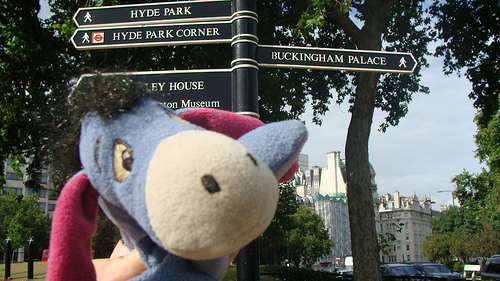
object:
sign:
[257, 41, 416, 72]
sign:
[69, 23, 235, 51]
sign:
[71, 3, 231, 21]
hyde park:
[124, 6, 191, 16]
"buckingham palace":
[265, 49, 389, 69]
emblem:
[396, 53, 412, 74]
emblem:
[262, 45, 425, 66]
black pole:
[231, 2, 258, 279]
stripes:
[228, 7, 258, 118]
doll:
[45, 84, 317, 279]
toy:
[45, 66, 312, 281]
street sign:
[66, 65, 233, 113]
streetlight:
[448, 189, 460, 209]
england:
[21, 8, 498, 268]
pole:
[232, 8, 262, 279]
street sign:
[70, 26, 247, 48]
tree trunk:
[340, 94, 382, 278]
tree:
[304, 6, 498, 279]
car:
[379, 260, 464, 280]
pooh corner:
[34, 62, 314, 279]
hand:
[107, 246, 247, 279]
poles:
[24, 218, 37, 281]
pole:
[230, 0, 259, 117]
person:
[77, 30, 90, 45]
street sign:
[258, 37, 417, 70]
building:
[368, 189, 430, 280]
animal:
[34, 99, 317, 274]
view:
[288, 150, 447, 272]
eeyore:
[37, 70, 309, 279]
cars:
[329, 262, 358, 278]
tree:
[5, 190, 49, 261]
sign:
[65, 67, 229, 114]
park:
[298, 250, 497, 277]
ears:
[232, 116, 308, 177]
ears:
[43, 169, 99, 277]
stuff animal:
[42, 71, 307, 276]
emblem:
[76, 29, 106, 45]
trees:
[7, 2, 427, 278]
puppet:
[45, 68, 307, 276]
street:
[314, 250, 497, 279]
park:
[1, 6, 361, 278]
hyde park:
[10, 7, 388, 276]